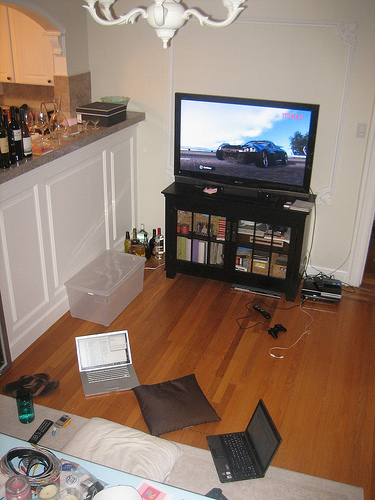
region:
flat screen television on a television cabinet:
[162, 92, 321, 302]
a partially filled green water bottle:
[14, 387, 34, 423]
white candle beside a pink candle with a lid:
[5, 473, 59, 498]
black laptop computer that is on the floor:
[203, 396, 281, 480]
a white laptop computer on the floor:
[73, 327, 137, 394]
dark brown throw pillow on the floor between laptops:
[75, 329, 281, 482]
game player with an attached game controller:
[236, 276, 342, 337]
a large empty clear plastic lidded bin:
[64, 249, 146, 326]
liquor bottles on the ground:
[124, 221, 165, 264]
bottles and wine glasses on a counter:
[1, 105, 45, 172]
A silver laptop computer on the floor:
[75, 327, 140, 395]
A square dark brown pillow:
[129, 370, 222, 438]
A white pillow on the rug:
[55, 413, 185, 487]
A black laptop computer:
[205, 398, 281, 484]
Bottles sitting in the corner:
[122, 221, 168, 260]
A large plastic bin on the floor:
[62, 248, 147, 327]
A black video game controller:
[266, 321, 286, 339]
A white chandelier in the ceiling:
[79, 0, 246, 49]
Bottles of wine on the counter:
[0, 102, 33, 170]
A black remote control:
[27, 417, 54, 443]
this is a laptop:
[133, 354, 332, 486]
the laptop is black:
[203, 403, 276, 494]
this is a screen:
[235, 373, 267, 487]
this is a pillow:
[135, 349, 207, 475]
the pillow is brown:
[142, 355, 212, 433]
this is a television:
[201, 108, 322, 217]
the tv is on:
[164, 126, 324, 233]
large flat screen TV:
[168, 87, 331, 211]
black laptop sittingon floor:
[200, 391, 300, 499]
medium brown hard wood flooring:
[151, 280, 372, 479]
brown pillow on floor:
[128, 360, 233, 444]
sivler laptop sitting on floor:
[65, 324, 156, 412]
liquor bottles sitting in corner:
[133, 210, 182, 281]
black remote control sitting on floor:
[247, 295, 274, 325]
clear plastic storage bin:
[60, 225, 163, 340]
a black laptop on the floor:
[201, 397, 285, 485]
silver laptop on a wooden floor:
[74, 328, 142, 399]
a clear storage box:
[65, 247, 147, 327]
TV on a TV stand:
[160, 91, 314, 303]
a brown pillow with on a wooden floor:
[132, 373, 220, 441]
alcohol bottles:
[121, 221, 168, 267]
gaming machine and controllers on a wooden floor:
[234, 272, 348, 362]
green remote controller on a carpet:
[14, 385, 36, 426]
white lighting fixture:
[78, 0, 247, 51]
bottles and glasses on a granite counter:
[0, 95, 71, 178]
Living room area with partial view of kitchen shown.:
[4, 3, 373, 499]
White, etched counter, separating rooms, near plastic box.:
[6, 149, 141, 327]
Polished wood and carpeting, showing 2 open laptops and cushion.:
[48, 329, 298, 483]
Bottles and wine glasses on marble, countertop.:
[6, 104, 106, 177]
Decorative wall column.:
[48, 23, 96, 108]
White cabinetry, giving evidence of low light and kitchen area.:
[4, 19, 51, 106]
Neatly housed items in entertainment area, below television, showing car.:
[169, 97, 315, 292]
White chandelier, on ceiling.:
[89, 3, 264, 41]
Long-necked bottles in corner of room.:
[124, 219, 166, 266]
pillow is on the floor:
[132, 364, 225, 448]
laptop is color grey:
[73, 330, 142, 398]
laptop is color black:
[204, 400, 283, 483]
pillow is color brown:
[132, 375, 220, 437]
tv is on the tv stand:
[162, 85, 324, 304]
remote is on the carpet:
[24, 421, 52, 446]